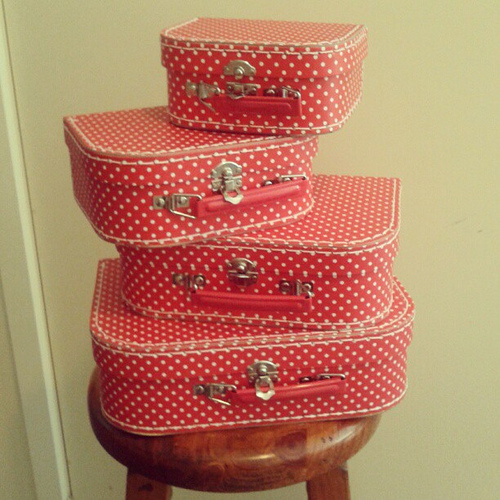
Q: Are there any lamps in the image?
A: No, there are no lamps.